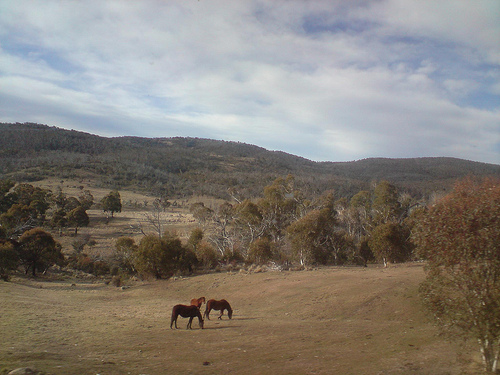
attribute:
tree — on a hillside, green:
[98, 187, 124, 219]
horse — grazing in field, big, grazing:
[201, 296, 236, 324]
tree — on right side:
[365, 219, 419, 266]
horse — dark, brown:
[166, 302, 206, 333]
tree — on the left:
[0, 238, 22, 285]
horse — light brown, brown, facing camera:
[187, 293, 209, 315]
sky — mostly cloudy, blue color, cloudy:
[1, 0, 499, 165]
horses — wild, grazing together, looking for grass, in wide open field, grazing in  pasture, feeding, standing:
[167, 294, 236, 333]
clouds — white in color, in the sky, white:
[1, 1, 500, 165]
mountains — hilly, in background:
[1, 121, 499, 260]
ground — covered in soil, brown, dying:
[1, 264, 499, 374]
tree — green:
[63, 204, 92, 238]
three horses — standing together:
[168, 292, 235, 330]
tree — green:
[15, 225, 71, 278]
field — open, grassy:
[1, 170, 499, 374]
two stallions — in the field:
[171, 298, 236, 330]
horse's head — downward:
[225, 305, 235, 321]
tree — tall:
[408, 171, 500, 374]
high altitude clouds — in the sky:
[1, 0, 499, 164]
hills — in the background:
[1, 120, 500, 267]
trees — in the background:
[0, 175, 433, 282]